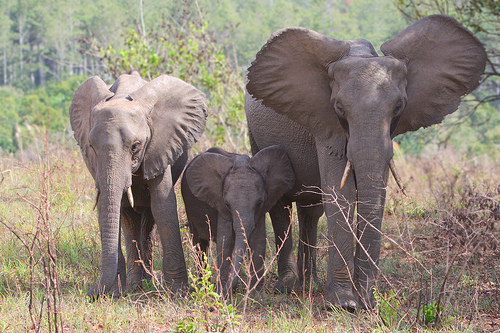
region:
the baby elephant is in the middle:
[188, 146, 297, 296]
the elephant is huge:
[248, 12, 484, 305]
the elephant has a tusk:
[120, 187, 147, 215]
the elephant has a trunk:
[347, 186, 397, 313]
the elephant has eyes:
[218, 191, 268, 213]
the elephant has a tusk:
[335, 161, 352, 193]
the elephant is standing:
[68, 65, 203, 302]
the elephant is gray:
[250, 14, 485, 331]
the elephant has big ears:
[246, 9, 498, 309]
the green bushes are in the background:
[11, 85, 56, 125]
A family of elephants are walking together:
[20, 4, 498, 330]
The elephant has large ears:
[245, 31, 358, 151]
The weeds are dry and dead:
[15, 140, 84, 332]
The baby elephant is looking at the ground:
[173, 137, 295, 292]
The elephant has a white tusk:
[115, 173, 139, 220]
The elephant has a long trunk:
[339, 150, 388, 332]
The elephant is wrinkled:
[247, 115, 302, 145]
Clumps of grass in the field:
[375, 287, 407, 330]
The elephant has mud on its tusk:
[334, 154, 349, 211]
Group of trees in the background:
[7, 2, 216, 91]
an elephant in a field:
[35, 57, 220, 300]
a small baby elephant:
[166, 135, 318, 292]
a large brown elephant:
[212, 10, 498, 317]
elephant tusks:
[331, 158, 360, 193]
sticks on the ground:
[14, 163, 94, 331]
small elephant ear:
[175, 131, 232, 240]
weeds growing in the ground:
[364, 270, 459, 332]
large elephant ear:
[213, 11, 359, 146]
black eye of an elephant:
[110, 125, 147, 175]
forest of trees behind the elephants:
[21, 10, 307, 72]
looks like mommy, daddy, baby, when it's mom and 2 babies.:
[65, 14, 490, 314]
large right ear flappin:
[405, 7, 491, 133]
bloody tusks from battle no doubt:
[337, 160, 409, 197]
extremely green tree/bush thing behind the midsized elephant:
[100, 19, 247, 109]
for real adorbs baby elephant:
[177, 142, 296, 304]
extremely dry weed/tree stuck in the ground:
[0, 127, 72, 331]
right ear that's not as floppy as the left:
[242, 26, 330, 123]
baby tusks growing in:
[87, 181, 138, 213]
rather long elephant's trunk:
[343, 135, 398, 316]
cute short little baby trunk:
[222, 217, 252, 301]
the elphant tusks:
[337, 156, 413, 201]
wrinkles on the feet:
[275, 254, 353, 288]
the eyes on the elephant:
[330, 92, 403, 128]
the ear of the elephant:
[237, 17, 330, 139]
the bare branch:
[352, 194, 482, 287]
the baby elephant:
[184, 137, 292, 292]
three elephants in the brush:
[24, 21, 490, 317]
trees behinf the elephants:
[9, 4, 214, 74]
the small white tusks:
[124, 179, 138, 209]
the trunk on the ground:
[82, 179, 126, 314]